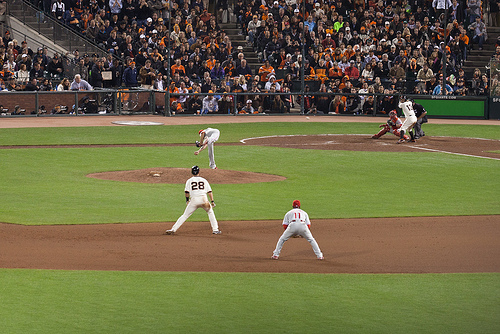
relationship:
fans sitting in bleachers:
[6, 1, 488, 113] [0, 1, 498, 120]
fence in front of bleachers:
[0, 88, 499, 118] [0, 1, 498, 120]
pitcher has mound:
[194, 126, 220, 168] [88, 165, 286, 185]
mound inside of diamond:
[88, 165, 286, 185] [0, 132, 498, 274]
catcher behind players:
[372, 110, 410, 142] [395, 95, 419, 144]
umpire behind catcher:
[410, 101, 427, 139] [372, 110, 410, 142]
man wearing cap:
[272, 200, 325, 259] [291, 200, 301, 207]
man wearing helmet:
[166, 165, 221, 235] [192, 165, 200, 176]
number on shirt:
[294, 211, 301, 220] [283, 208, 311, 224]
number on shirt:
[190, 180, 205, 191] [185, 176, 214, 199]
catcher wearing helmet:
[372, 110, 410, 142] [388, 108, 399, 119]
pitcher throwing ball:
[194, 126, 220, 168] [305, 115, 311, 120]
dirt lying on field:
[0, 216, 499, 273] [0, 122, 500, 333]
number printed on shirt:
[190, 180, 205, 191] [185, 176, 214, 199]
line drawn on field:
[411, 144, 500, 164] [0, 122, 500, 333]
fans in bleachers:
[6, 1, 488, 113] [0, 1, 498, 120]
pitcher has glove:
[194, 126, 220, 168] [194, 140, 203, 147]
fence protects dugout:
[0, 88, 499, 118] [0, 91, 167, 116]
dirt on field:
[0, 216, 499, 273] [0, 122, 500, 333]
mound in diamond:
[88, 165, 286, 185] [0, 132, 498, 274]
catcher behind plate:
[372, 110, 410, 142] [373, 138, 389, 149]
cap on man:
[291, 200, 301, 207] [272, 200, 325, 259]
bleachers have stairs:
[0, 1, 498, 120] [0, 1, 129, 85]